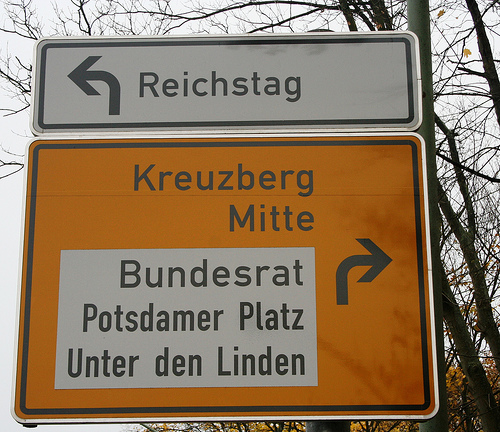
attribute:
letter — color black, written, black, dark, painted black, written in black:
[138, 70, 161, 101]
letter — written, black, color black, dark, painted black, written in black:
[160, 77, 180, 98]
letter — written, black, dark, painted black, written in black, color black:
[180, 68, 191, 99]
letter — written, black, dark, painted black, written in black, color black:
[191, 76, 211, 100]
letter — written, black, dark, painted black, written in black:
[208, 68, 229, 99]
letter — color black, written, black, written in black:
[231, 75, 251, 99]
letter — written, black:
[248, 70, 263, 98]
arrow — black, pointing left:
[66, 55, 121, 117]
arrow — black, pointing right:
[337, 238, 393, 306]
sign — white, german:
[30, 30, 422, 136]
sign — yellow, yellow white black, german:
[10, 131, 441, 423]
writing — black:
[135, 68, 304, 105]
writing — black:
[131, 161, 316, 234]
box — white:
[53, 246, 320, 392]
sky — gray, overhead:
[1, 1, 499, 355]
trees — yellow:
[145, 367, 499, 432]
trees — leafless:
[1, 2, 499, 354]